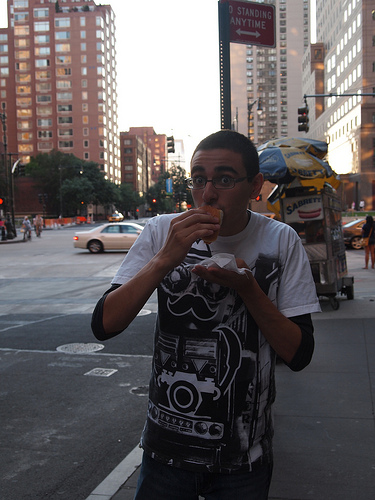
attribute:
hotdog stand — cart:
[276, 180, 355, 309]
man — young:
[91, 130, 322, 499]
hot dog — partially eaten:
[195, 201, 224, 245]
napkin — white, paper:
[185, 250, 251, 274]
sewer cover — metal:
[57, 338, 105, 359]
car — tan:
[72, 220, 148, 256]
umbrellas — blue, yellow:
[255, 133, 339, 215]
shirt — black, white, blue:
[360, 219, 374, 245]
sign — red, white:
[228, 0, 277, 50]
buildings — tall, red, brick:
[1, 1, 167, 229]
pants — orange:
[361, 242, 374, 271]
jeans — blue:
[133, 449, 273, 499]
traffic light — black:
[293, 97, 310, 135]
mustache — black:
[163, 291, 219, 322]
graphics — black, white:
[139, 238, 281, 469]